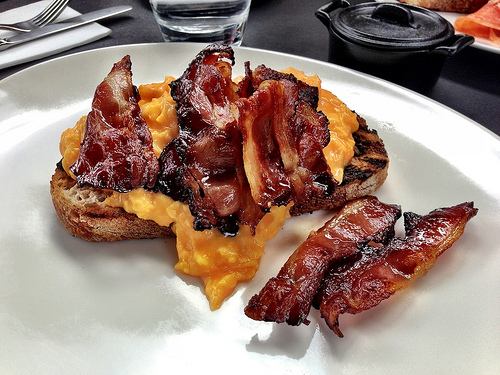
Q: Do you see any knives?
A: Yes, there is a knife.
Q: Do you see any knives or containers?
A: Yes, there is a knife.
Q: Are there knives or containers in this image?
A: Yes, there is a knife.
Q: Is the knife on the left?
A: Yes, the knife is on the left of the image.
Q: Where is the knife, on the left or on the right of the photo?
A: The knife is on the left of the image.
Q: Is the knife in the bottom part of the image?
A: No, the knife is in the top of the image.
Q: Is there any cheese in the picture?
A: Yes, there is cheese.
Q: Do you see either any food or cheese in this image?
A: Yes, there is cheese.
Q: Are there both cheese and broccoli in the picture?
A: No, there is cheese but no broccoli.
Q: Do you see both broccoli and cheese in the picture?
A: No, there is cheese but no broccoli.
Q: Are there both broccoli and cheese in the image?
A: No, there is cheese but no broccoli.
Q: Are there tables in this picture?
A: Yes, there is a table.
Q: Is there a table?
A: Yes, there is a table.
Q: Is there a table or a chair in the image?
A: Yes, there is a table.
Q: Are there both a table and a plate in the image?
A: Yes, there are both a table and a plate.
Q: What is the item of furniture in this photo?
A: The piece of furniture is a table.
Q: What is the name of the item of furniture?
A: The piece of furniture is a table.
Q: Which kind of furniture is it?
A: The piece of furniture is a table.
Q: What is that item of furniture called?
A: This is a table.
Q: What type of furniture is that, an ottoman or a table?
A: This is a table.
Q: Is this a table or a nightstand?
A: This is a table.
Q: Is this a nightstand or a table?
A: This is a table.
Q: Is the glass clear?
A: Yes, the glass is clear.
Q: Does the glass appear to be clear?
A: Yes, the glass is clear.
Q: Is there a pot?
A: Yes, there is a pot.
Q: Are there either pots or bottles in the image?
A: Yes, there is a pot.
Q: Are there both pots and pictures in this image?
A: No, there is a pot but no pictures.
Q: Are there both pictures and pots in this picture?
A: No, there is a pot but no pictures.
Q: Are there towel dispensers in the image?
A: No, there are no towel dispensers.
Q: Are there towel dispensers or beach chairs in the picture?
A: No, there are no towel dispensers or beach chairs.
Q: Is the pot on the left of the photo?
A: No, the pot is on the right of the image.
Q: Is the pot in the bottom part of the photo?
A: No, the pot is in the top of the image.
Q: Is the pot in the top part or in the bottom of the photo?
A: The pot is in the top of the image.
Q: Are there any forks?
A: Yes, there is a fork.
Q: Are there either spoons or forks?
A: Yes, there is a fork.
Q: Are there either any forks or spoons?
A: Yes, there is a fork.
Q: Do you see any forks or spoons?
A: Yes, there is a fork.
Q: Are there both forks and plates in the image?
A: Yes, there are both a fork and a plate.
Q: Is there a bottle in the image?
A: No, there are no bottles.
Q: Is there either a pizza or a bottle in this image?
A: No, there are no bottles or pizzas.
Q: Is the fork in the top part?
A: Yes, the fork is in the top of the image.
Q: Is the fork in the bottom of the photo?
A: No, the fork is in the top of the image.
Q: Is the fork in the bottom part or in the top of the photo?
A: The fork is in the top of the image.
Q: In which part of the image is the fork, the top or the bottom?
A: The fork is in the top of the image.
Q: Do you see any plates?
A: Yes, there is a plate.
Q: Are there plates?
A: Yes, there is a plate.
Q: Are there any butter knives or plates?
A: Yes, there is a plate.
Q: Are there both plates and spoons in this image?
A: No, there is a plate but no spoons.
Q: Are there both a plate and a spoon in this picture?
A: No, there is a plate but no spoons.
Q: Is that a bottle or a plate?
A: That is a plate.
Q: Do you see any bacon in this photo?
A: Yes, there is bacon.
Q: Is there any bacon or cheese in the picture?
A: Yes, there is bacon.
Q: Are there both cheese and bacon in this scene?
A: Yes, there are both bacon and cheese.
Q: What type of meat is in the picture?
A: The meat is bacon.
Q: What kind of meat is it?
A: The meat is bacon.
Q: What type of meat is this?
A: This is bacon.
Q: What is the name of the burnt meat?
A: The meat is bacon.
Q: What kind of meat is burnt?
A: The meat is bacon.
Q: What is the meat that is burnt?
A: The meat is bacon.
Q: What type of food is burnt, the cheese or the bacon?
A: The bacon is burnt.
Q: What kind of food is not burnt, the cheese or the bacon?
A: The cheese is not burnt.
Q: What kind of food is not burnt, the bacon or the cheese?
A: The cheese is not burnt.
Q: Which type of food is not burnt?
A: The food is cheese.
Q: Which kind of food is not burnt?
A: The food is cheese.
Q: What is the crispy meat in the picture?
A: The meat is bacon.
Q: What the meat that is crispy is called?
A: The meat is bacon.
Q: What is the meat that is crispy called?
A: The meat is bacon.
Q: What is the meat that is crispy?
A: The meat is bacon.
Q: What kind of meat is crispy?
A: The meat is bacon.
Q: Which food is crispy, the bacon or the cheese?
A: The bacon is crispy.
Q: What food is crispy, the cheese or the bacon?
A: The bacon is crispy.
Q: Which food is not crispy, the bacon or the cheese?
A: The cheese is not crispy.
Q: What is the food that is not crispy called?
A: The food is cheese.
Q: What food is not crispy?
A: The food is cheese.